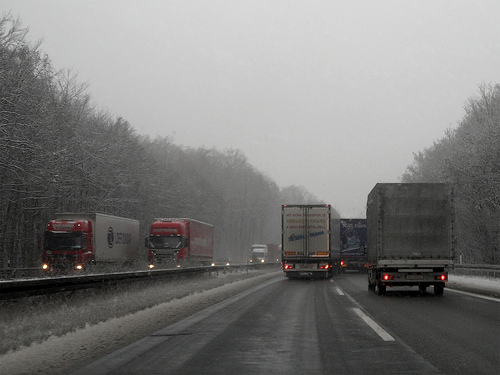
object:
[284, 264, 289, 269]
break light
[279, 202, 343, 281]
truck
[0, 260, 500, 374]
road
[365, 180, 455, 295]
truck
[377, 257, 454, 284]
bumper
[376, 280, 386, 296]
tire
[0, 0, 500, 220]
sky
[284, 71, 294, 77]
clouds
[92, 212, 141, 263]
trailer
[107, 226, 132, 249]
writing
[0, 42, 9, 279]
trees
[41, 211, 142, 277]
trucks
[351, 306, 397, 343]
lines